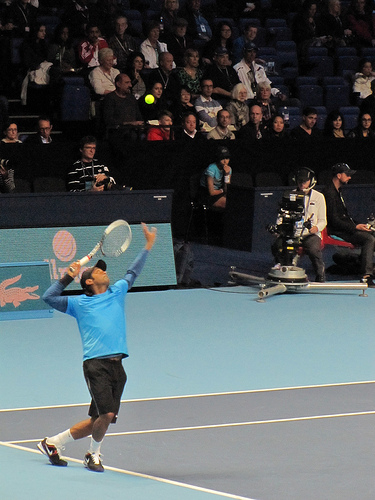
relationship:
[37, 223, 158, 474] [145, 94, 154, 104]
tennis player hitting tennis ball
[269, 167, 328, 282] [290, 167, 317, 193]
person with headset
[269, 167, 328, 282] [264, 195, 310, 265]
person with camera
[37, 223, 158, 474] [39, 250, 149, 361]
tennis player has shirt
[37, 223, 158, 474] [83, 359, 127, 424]
tennis player wears shorts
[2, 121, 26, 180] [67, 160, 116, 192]
woman wears sweater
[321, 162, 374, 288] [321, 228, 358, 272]
man in chair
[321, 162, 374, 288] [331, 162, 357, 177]
man wearing cap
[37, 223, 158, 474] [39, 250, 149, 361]
tennis player with shirt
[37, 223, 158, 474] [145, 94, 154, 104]
tennis player hit tennis ball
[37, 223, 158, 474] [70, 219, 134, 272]
tennis player has racket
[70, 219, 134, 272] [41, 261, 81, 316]
racket in arm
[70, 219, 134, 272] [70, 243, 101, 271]
racket has handle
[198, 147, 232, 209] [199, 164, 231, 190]
viewer has shirt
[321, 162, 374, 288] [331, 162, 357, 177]
man wears cap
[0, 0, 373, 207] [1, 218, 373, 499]
viewers watching tennis match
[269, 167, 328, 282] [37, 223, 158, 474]
person filming tennis player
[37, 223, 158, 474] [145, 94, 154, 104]
tennis player serving tennis ball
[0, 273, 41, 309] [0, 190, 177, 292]
logo on wall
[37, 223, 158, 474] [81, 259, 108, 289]
tennis player wearing cap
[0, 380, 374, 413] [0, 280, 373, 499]
line on tennis court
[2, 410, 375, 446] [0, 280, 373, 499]
line on tennis court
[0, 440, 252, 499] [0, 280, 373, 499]
line on tennis court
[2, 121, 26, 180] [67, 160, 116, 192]
woman wearing sweater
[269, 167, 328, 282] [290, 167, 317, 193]
person wearing headset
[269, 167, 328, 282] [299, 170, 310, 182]
person wearing cap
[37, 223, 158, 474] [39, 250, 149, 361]
tennis player wearing shirt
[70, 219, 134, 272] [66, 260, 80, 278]
racket in hand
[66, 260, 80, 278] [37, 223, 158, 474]
hand of tennis player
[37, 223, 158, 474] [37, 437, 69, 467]
tennis player wearing shoe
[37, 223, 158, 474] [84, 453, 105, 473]
tennis player wearing shoe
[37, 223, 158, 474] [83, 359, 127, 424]
tennis player wearing shorts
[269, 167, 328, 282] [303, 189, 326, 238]
person wearing shirt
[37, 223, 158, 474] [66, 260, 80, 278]
tennis player holds up hand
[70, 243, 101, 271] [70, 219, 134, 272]
handle of racket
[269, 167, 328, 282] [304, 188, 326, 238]
person wears jacket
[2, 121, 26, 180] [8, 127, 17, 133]
woman wears glasses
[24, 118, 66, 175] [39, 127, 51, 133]
man wears glasses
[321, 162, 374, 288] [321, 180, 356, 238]
man wears jacket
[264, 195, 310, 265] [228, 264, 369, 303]
camera on support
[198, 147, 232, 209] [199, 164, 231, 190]
girl wears shirt